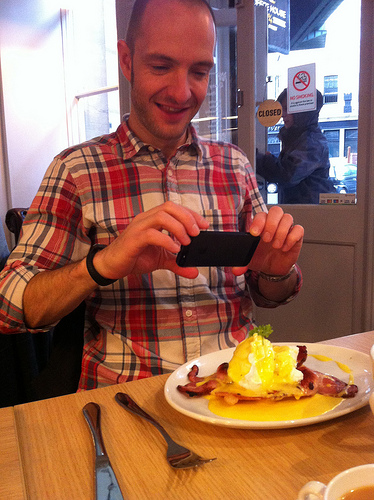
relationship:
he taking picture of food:
[0, 0, 303, 393] [176, 324, 358, 421]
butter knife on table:
[82, 402, 125, 500] [2, 333, 371, 498]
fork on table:
[114, 392, 217, 471] [2, 333, 371, 498]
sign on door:
[253, 93, 286, 140] [235, 13, 371, 301]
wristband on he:
[74, 239, 113, 289] [0, 0, 303, 393]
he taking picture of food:
[0, 0, 303, 393] [174, 324, 361, 429]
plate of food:
[164, 342, 374, 429] [178, 333, 356, 401]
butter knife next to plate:
[82, 402, 125, 500] [164, 342, 374, 429]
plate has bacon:
[163, 341, 362, 430] [175, 345, 358, 398]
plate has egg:
[163, 341, 362, 430] [226, 332, 303, 392]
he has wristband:
[0, 0, 303, 393] [86, 243, 118, 286]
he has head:
[0, 0, 303, 393] [112, 0, 220, 144]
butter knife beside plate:
[82, 402, 125, 500] [163, 341, 362, 430]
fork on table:
[114, 387, 214, 472] [2, 333, 371, 498]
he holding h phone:
[0, 0, 303, 393] [173, 221, 262, 270]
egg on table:
[196, 332, 353, 422] [0, 329, 374, 499]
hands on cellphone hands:
[107, 197, 313, 279] [127, 208, 328, 291]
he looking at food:
[0, 0, 303, 393] [178, 327, 360, 413]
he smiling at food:
[0, 0, 303, 393] [178, 327, 360, 413]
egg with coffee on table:
[196, 332, 353, 422] [31, 316, 371, 482]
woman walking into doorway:
[241, 81, 341, 206] [228, 3, 370, 345]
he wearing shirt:
[0, 0, 303, 393] [2, 114, 302, 391]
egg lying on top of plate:
[196, 332, 353, 422] [163, 341, 362, 430]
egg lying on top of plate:
[272, 340, 303, 384] [163, 341, 362, 430]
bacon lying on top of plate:
[175, 345, 358, 398] [163, 341, 362, 430]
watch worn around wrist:
[260, 264, 297, 282] [260, 265, 298, 282]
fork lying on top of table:
[114, 392, 217, 471] [2, 333, 371, 498]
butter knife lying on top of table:
[82, 402, 125, 500] [2, 333, 371, 498]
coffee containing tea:
[299, 464, 373, 500] [336, 486, 362, 497]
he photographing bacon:
[0, 0, 303, 393] [294, 341, 320, 399]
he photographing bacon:
[0, 0, 303, 393] [311, 366, 362, 398]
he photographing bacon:
[0, 0, 303, 393] [178, 361, 231, 401]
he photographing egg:
[0, 0, 303, 393] [226, 332, 278, 389]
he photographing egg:
[0, 0, 303, 393] [272, 340, 303, 384]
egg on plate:
[196, 332, 353, 422] [163, 341, 362, 430]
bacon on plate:
[175, 345, 358, 398] [163, 341, 362, 430]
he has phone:
[7, 8, 316, 396] [176, 230, 262, 267]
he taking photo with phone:
[7, 8, 316, 396] [176, 230, 262, 267]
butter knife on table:
[79, 402, 125, 498] [7, 402, 70, 498]